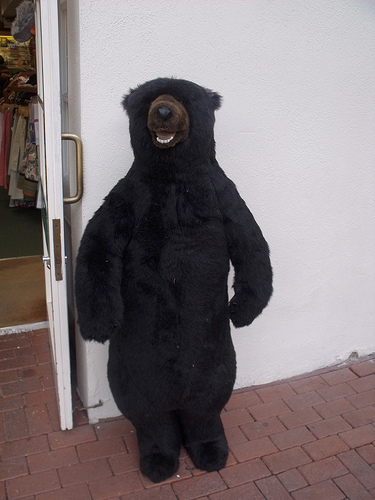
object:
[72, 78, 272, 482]
bear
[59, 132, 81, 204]
handle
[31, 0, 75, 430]
door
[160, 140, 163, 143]
teeth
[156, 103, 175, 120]
nose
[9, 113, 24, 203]
clothes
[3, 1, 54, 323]
inside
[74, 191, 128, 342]
arm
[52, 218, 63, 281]
plate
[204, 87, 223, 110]
ear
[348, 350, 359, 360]
hole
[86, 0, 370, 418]
wall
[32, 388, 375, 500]
sidewalk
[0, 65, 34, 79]
rack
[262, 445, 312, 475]
tile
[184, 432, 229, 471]
feet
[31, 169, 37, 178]
flowers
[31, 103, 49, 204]
garment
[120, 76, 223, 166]
head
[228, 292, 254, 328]
paws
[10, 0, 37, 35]
items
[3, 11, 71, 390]
sale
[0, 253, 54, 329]
floor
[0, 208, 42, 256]
carpet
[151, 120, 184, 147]
mouth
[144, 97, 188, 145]
snout